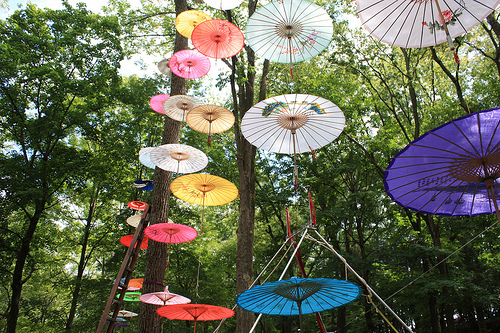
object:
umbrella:
[234, 272, 366, 317]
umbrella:
[379, 106, 500, 218]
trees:
[3, 0, 120, 332]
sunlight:
[114, 46, 158, 78]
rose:
[425, 7, 465, 35]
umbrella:
[350, 0, 497, 51]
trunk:
[226, 0, 265, 331]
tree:
[140, 0, 192, 330]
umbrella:
[167, 170, 241, 207]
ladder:
[94, 201, 150, 333]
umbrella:
[152, 301, 235, 324]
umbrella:
[141, 221, 200, 247]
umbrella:
[242, 0, 338, 68]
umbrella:
[115, 290, 142, 304]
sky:
[121, 62, 133, 74]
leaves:
[19, 6, 92, 61]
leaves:
[337, 81, 365, 109]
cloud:
[27, 1, 65, 8]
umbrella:
[184, 100, 236, 138]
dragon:
[260, 100, 328, 118]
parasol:
[240, 92, 348, 157]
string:
[305, 191, 321, 226]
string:
[361, 287, 396, 331]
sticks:
[282, 221, 325, 242]